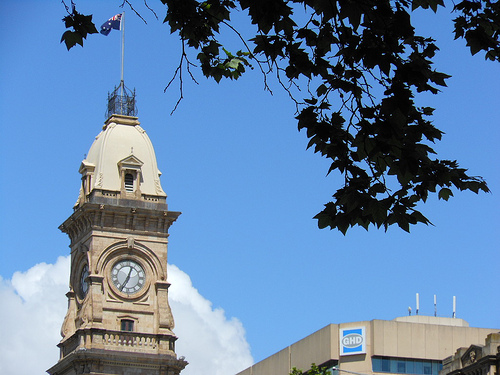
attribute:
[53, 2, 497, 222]
leaves — green 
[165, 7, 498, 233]
leaves — dark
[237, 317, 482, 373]
building — concrete 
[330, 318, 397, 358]
sign — blue, white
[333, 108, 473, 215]
leaves — green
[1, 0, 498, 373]
blue sky — clear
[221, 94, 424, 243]
sky — blue 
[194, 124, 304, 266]
sky — blue 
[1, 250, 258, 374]
cloud — white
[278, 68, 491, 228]
leaves — green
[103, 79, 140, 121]
decoration — black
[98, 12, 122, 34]
flag — small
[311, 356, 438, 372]
panes — glass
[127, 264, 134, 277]
hand — black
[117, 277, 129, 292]
hand — black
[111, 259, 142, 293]
numerals — roman